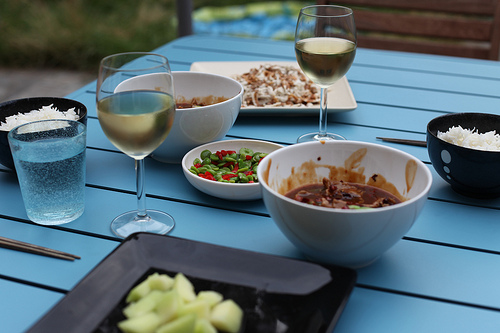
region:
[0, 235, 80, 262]
Pair of chopsticks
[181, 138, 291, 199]
Vegetables in a small white bowl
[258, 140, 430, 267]
Pork strips in barbecue sauce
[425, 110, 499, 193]
Black bowl filled with white rice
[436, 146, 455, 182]
Three gray circles on a black bowl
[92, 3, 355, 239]
Two half full glasses of white wine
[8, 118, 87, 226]
Speckled glass of water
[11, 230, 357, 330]
Chopped food on a rectangular black dish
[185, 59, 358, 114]
White square serving plate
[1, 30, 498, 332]
Blue painted wood table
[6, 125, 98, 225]
a small glass of seltzer water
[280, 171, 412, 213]
red beans in a bowl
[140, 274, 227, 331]
white chunks of apple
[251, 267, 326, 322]
a shiny black ceramic plate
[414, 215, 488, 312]
a wooden blue table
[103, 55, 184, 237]
a glass of white wine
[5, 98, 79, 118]
a black bowl of white rice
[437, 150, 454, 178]
gray circles on the bowl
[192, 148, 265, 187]
red and green peppers in a bowl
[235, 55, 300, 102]
a plate of rice and beans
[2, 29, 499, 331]
A blue wooden tabletop.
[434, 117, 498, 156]
White rice.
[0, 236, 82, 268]
A pair of wooden chopsticks.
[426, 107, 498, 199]
A black bowl.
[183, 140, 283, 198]
A small flat white bowl.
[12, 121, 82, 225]
A small clear glass.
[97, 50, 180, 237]
A wine glass.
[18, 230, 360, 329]
A black square plate.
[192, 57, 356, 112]
A white square plate.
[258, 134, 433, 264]
A large white bowl.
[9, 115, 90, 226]
a small clear drinking glass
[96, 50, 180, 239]
a tall stemmed glass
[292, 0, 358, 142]
a tall stemmed glass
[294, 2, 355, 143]
a glass of white wine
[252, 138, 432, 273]
a large white bowl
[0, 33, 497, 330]
a bright blue table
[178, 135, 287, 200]
a small white dish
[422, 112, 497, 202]
a small black bowl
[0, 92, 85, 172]
a small black bowl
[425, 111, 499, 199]
Black bowl with rice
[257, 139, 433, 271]
White bowl with brown gravy and meat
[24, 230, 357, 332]
Black square bowl with food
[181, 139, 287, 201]
White bowl with beans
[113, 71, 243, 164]
White round bowl with food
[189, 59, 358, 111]
White square bowl with food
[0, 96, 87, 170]
Black round bowl with white rice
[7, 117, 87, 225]
Clear glass with water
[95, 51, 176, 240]
Tall clear half full glass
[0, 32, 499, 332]
Large light blue table